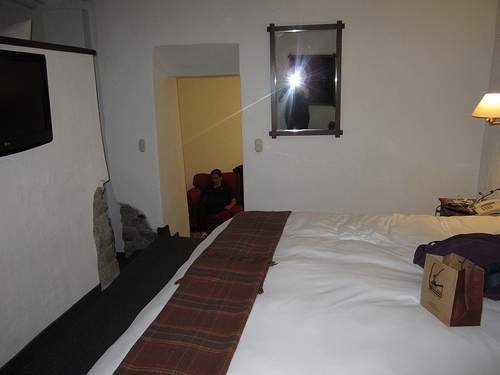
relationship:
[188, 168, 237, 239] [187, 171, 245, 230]
person sitting on sofa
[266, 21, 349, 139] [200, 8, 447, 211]
mirror on wall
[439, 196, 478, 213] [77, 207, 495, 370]
table next to bed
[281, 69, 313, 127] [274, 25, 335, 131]
person in mirror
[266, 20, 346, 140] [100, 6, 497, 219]
mirror on wall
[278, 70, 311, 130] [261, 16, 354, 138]
person on mirror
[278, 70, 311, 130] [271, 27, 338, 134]
person on mirror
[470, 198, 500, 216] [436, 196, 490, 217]
phone on table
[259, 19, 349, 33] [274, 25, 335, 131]
frame of mirror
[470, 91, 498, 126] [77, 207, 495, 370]
lamp by bed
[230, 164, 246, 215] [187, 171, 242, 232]
person on sofa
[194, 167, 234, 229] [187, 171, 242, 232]
person on sofa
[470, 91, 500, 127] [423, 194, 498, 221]
lamp on table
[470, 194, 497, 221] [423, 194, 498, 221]
phone on table